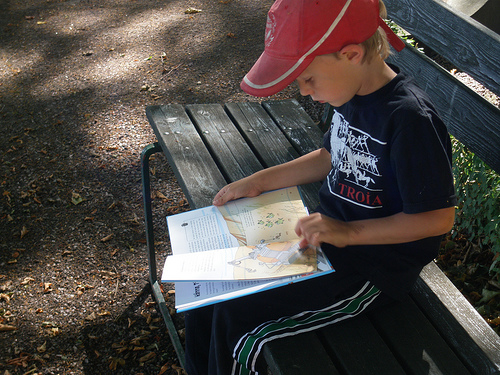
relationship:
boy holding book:
[171, 1, 470, 375] [152, 183, 341, 318]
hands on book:
[208, 173, 344, 259] [152, 183, 341, 318]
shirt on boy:
[305, 63, 461, 299] [171, 1, 470, 375]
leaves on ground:
[13, 132, 121, 320] [1, 1, 340, 374]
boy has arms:
[171, 1, 470, 375] [220, 128, 459, 252]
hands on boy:
[208, 173, 344, 259] [171, 1, 470, 375]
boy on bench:
[171, 1, 470, 375] [117, 1, 500, 369]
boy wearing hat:
[171, 1, 470, 375] [236, 2, 412, 109]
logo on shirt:
[322, 106, 390, 212] [305, 63, 461, 299]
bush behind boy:
[416, 102, 497, 315] [171, 1, 470, 375]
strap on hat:
[370, 10, 408, 51] [236, 2, 412, 109]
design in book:
[210, 208, 304, 253] [152, 183, 341, 318]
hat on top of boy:
[236, 2, 412, 109] [171, 1, 470, 375]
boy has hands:
[171, 1, 470, 375] [208, 173, 344, 259]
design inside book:
[210, 208, 304, 253] [152, 183, 341, 318]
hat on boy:
[236, 2, 412, 109] [171, 1, 470, 375]